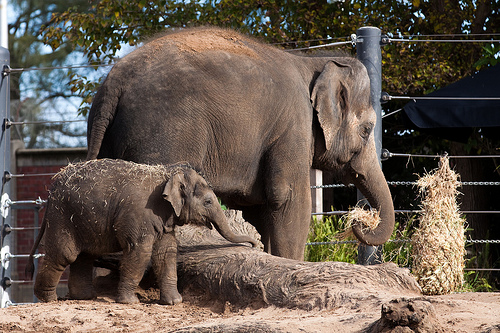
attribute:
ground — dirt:
[3, 286, 495, 331]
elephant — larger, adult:
[88, 25, 396, 263]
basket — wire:
[410, 150, 473, 292]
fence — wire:
[358, 27, 499, 280]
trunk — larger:
[352, 154, 394, 249]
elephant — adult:
[82, 30, 399, 277]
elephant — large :
[35, 143, 275, 317]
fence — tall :
[396, 37, 481, 144]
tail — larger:
[83, 102, 114, 165]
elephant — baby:
[71, 50, 439, 209]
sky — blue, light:
[7, 7, 19, 23]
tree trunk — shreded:
[407, 166, 468, 288]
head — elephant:
[149, 146, 264, 258]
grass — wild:
[379, 207, 444, 278]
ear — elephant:
[311, 59, 358, 158]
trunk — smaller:
[212, 203, 262, 249]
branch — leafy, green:
[3, 8, 135, 78]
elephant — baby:
[153, 165, 198, 226]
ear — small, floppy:
[158, 170, 188, 220]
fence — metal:
[2, 21, 499, 299]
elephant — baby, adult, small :
[25, 156, 263, 306]